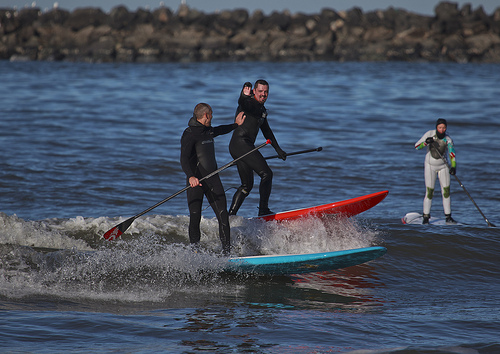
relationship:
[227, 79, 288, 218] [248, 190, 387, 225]
boarder on paddle board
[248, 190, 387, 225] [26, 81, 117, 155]
paddle board on water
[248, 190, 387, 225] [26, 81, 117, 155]
paddle board in water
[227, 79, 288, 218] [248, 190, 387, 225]
boarder in paddle board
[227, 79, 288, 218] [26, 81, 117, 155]
boarder in water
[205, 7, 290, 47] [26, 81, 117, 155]
rocks behind water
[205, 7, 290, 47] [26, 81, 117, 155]
rocks on water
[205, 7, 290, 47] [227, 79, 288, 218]
rocks behind boarder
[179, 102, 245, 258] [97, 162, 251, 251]
boarders holds paddle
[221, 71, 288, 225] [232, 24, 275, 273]
boarder in middle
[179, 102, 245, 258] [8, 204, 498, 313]
boarders on wave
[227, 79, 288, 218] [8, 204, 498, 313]
boarder on wave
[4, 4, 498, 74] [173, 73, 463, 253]
rock jetty behind boarders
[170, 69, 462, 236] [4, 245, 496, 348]
boarders on water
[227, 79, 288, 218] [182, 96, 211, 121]
boarder has hair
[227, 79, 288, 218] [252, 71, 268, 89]
boarder has hair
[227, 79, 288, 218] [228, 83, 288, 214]
boarder wears wet suit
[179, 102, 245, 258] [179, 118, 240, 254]
boarders wears wet suit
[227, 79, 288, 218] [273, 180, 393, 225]
boarder on surfboard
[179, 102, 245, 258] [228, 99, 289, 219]
boarders wears wet suit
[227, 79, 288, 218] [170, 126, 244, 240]
boarder wears wet suit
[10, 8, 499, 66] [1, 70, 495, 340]
rocks in ocean